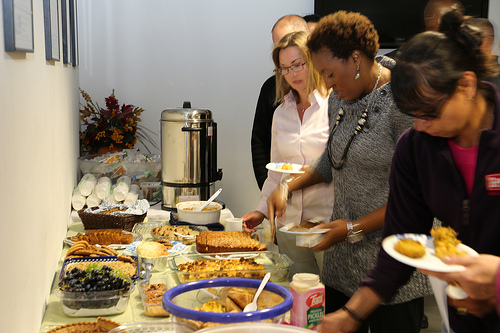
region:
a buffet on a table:
[160, 272, 297, 327]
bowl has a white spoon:
[157, 269, 300, 322]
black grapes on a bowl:
[46, 261, 137, 313]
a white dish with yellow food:
[377, 196, 490, 282]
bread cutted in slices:
[189, 217, 274, 256]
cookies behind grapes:
[55, 229, 133, 266]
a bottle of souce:
[285, 263, 330, 329]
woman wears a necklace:
[298, 10, 398, 177]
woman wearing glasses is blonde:
[264, 27, 329, 109]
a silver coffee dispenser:
[148, 98, 229, 198]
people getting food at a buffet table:
[42, 0, 497, 330]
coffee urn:
[156, 98, 223, 212]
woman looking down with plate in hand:
[381, 13, 495, 274]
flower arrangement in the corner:
[73, 80, 150, 175]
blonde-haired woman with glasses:
[267, 27, 311, 173]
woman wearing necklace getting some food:
[298, 9, 385, 258]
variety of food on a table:
[53, 212, 328, 331]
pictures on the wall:
[0, 0, 87, 70]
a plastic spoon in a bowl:
[166, 277, 300, 322]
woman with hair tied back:
[387, 0, 493, 147]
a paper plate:
[373, 219, 491, 269]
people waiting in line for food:
[247, 10, 498, 307]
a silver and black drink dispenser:
[155, 92, 228, 209]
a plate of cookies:
[66, 240, 127, 261]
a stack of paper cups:
[73, 180, 142, 208]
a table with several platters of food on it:
[73, 203, 298, 331]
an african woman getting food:
[293, 12, 418, 325]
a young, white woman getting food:
[266, 36, 343, 261]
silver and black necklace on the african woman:
[314, 62, 386, 169]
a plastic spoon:
[229, 268, 278, 313]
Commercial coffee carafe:
[152, 89, 230, 215]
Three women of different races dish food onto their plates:
[260, 20, 495, 230]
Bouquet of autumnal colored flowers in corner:
[73, 75, 144, 160]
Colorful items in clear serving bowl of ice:
[78, 141, 168, 182]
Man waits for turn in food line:
[252, 5, 312, 217]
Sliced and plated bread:
[186, 226, 276, 262]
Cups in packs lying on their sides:
[70, 163, 141, 209]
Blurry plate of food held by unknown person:
[372, 215, 493, 293]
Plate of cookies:
[62, 236, 138, 268]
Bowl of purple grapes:
[53, 262, 135, 315]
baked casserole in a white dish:
[168, 252, 293, 275]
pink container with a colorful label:
[287, 273, 326, 328]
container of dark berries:
[57, 258, 135, 315]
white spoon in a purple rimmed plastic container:
[243, 267, 278, 314]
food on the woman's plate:
[381, 209, 482, 277]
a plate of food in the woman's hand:
[380, 215, 484, 282]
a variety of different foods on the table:
[50, 195, 289, 332]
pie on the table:
[40, 317, 120, 331]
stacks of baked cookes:
[63, 235, 134, 261]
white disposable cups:
[72, 168, 136, 209]